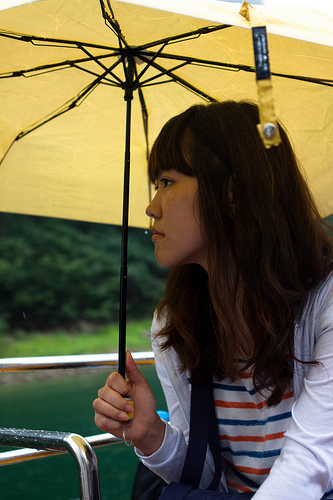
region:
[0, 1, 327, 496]
a girl holding an umbrella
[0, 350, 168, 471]
a metal railing behind the girl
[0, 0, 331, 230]
the umbrella is yellow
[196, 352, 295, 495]
her shirt is striped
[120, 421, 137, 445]
a ring on the end of the umbrella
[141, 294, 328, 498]
she is wearing a white jacket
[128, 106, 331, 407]
her hair is long and dark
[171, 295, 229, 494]
a black strap over her shoulder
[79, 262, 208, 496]
her right hand holding the umbrella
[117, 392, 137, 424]
the umbrella handle is yellow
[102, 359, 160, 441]
women holding an umbrella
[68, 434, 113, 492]
a pole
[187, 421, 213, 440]
a blue strap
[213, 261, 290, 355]
the womens hair is brown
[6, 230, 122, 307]
a green bush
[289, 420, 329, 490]
a white sleeve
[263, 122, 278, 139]
a button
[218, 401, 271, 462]
red and blue stripes on the shirt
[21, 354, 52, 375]
a pole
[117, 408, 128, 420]
fingernails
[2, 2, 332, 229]
tan fabric and metal umbrella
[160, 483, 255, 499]
navy blue hand bag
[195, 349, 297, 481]
striped cotton tee shirt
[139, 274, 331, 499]
white cotton sweat shirt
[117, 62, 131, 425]
black metal umbrella handle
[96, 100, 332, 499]
woman sitting on seat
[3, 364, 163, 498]
lake next to trees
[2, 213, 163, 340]
trees with green leaves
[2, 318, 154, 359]
green grass by water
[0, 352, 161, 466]
silver metal tube railing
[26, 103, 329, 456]
A young woman under an umbrella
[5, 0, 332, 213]
A yellow umbrella over the woman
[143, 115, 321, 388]
Shoulder length hair on the young woman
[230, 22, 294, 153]
A yellow and black strap on the umbrella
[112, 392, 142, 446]
The yellow handle of the umbrella in the woman's hand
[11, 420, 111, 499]
A thin metal pole in front of the woman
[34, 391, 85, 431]
The water looks calm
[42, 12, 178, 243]
The black plastic spine of the umbrella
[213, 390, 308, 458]
Blue and red stripes on the white shirt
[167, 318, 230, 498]
A blue strap over the woman's shoulder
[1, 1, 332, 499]
a woman holding a yellow umbrella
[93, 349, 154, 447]
a woman's hand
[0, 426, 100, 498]
a wet curved metal rail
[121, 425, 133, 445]
a small metal ring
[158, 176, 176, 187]
eye of a woman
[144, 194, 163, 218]
nose of a woman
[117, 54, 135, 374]
black metal rod for an umbrella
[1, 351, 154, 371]
a metal rod for a railing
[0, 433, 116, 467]
a metal rod for a railing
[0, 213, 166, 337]
foliage in the distance